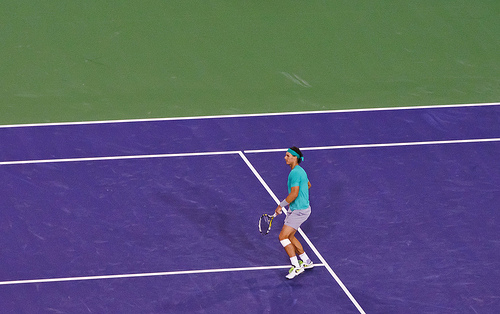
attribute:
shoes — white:
[281, 250, 317, 283]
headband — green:
[284, 146, 304, 161]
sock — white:
[278, 252, 320, 272]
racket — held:
[245, 204, 283, 240]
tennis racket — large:
[261, 210, 273, 228]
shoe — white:
[282, 255, 300, 280]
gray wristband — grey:
[277, 195, 291, 213]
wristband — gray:
[278, 205, 288, 212]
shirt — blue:
[284, 164, 314, 214]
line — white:
[0, 74, 480, 292]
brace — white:
[278, 238, 291, 245]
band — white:
[278, 237, 290, 245]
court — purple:
[1, 97, 498, 311]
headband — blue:
[283, 145, 301, 158]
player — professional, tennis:
[262, 141, 322, 288]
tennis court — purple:
[2, 98, 498, 312]